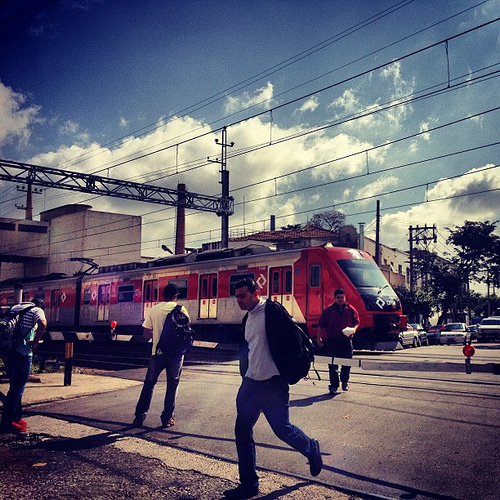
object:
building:
[201, 214, 454, 295]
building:
[1, 202, 142, 284]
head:
[234, 278, 258, 310]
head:
[334, 289, 346, 304]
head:
[162, 283, 180, 302]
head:
[31, 297, 46, 311]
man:
[317, 289, 361, 394]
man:
[2, 298, 48, 433]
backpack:
[0, 305, 35, 355]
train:
[1, 246, 407, 355]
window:
[203, 278, 207, 297]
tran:
[81, 240, 405, 343]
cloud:
[0, 83, 45, 153]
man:
[222, 279, 323, 496]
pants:
[234, 376, 317, 487]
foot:
[223, 480, 259, 497]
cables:
[0, 0, 497, 270]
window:
[229, 272, 252, 295]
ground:
[3, 325, 498, 495]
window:
[212, 278, 217, 297]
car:
[439, 323, 472, 346]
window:
[331, 259, 389, 291]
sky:
[3, 6, 498, 125]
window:
[310, 264, 320, 287]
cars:
[476, 316, 500, 343]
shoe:
[307, 439, 324, 476]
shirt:
[244, 297, 280, 381]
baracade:
[108, 332, 498, 374]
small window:
[117, 285, 135, 303]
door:
[198, 273, 218, 320]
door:
[266, 265, 293, 315]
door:
[143, 278, 159, 319]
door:
[96, 283, 110, 321]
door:
[50, 289, 61, 323]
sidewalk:
[3, 343, 494, 498]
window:
[285, 270, 292, 292]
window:
[169, 279, 187, 301]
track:
[0, 353, 500, 400]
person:
[132, 283, 193, 426]